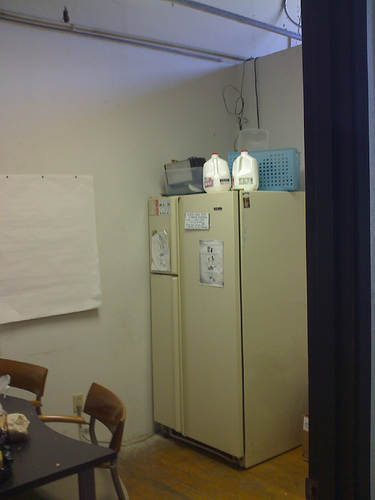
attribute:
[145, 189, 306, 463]
refrigerator — tall, beige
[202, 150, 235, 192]
milk — gallon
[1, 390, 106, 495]
table — black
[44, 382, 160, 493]
chair — brown, wooden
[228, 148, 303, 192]
container — blue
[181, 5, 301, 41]
pipes — metal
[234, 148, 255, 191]
milk — gallon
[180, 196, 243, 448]
door — beige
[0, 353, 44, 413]
chair — wooden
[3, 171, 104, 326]
paper — white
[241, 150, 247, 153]
cap — red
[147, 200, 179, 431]
freezer — large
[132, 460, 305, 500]
floor — wooden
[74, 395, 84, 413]
socket — electric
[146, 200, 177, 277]
door — top